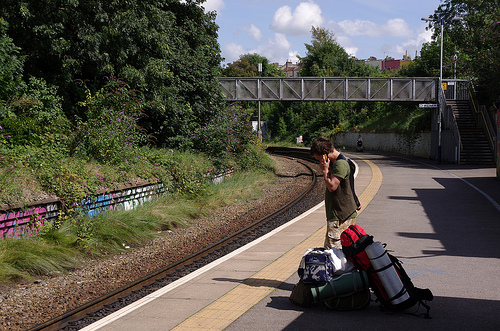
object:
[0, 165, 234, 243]
wall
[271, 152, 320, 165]
tracks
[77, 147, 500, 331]
walkway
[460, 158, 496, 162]
stairs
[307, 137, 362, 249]
man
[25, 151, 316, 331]
track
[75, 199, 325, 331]
curb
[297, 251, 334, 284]
luggage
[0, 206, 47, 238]
graffiti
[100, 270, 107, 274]
rock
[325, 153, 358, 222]
shirt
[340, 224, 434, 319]
backpack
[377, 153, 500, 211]
line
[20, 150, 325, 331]
railroad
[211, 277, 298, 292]
shadow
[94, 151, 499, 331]
pavement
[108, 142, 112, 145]
leave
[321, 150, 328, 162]
phone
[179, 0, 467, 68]
sky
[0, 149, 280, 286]
grass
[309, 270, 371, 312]
suitcase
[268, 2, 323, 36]
cloud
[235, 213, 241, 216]
gravel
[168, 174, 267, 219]
side